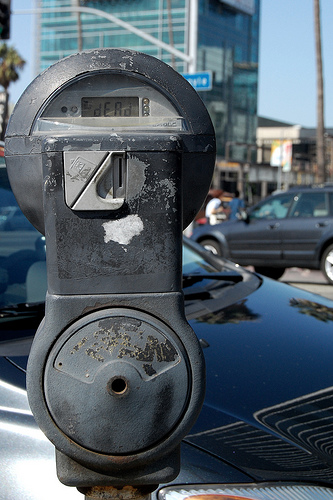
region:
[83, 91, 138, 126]
word on the meter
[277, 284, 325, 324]
reflection in the car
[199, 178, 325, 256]
car near another car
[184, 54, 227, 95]
sign near the meter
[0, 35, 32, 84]
tree near the car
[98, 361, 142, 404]
hole in the meter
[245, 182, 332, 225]
windows on side of car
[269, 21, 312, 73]
sky above the land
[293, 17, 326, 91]
branch of a tree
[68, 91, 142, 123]
"dEAd" is written on the meter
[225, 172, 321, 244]
Vehicle in the background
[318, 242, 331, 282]
Wheel of a vehicle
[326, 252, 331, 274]
Rim of a tire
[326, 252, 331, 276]
Silver rim of a tire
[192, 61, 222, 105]
Street sign in the distance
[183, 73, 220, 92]
The sign has white lettering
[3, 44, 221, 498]
black parking meter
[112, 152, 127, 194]
coin slot on parking meter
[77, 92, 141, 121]
digital window on parking meter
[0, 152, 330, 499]
car parked behind parking meter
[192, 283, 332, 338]
reflection of trees in hood of car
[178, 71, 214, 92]
blue and white street sign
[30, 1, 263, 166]
tall metal and glass building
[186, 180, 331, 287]
grey four door suv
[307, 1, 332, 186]
tall wooden pole upright on sidewalk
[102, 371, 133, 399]
hole in center of bottom of parking meter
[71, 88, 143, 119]
word dead on the parking meter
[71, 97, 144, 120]
word dead on the parking meter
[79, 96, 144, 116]
word dead on the parking meter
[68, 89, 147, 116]
word dead on the parking meter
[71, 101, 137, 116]
word dead on the parking meter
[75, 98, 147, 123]
word dead on the parking meter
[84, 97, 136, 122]
word dead on the parking meter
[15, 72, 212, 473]
the parking mete is gray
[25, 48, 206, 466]
the parking mete is gray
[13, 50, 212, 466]
the parking mete is gray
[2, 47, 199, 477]
the parking mete is gray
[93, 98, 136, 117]
letters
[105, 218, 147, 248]
white paper on the meter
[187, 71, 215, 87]
a blue sign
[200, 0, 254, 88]
a building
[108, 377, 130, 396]
a small hole on the meter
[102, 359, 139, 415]
a hole in the meter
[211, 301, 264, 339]
a green tree in he reflection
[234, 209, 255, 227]
the suv mirror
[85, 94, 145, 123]
the sign says dead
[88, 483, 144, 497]
the meter is rusted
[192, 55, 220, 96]
a blue sign in the background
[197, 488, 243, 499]
the headlight of the car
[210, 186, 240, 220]
people in the background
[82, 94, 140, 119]
digital screen on the parking meter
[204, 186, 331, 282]
dark grey suv on the street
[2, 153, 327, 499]
car behind the parking meter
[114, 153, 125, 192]
coin slot on the parking meter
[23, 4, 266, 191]
tall building behind the parking meter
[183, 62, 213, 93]
blue and white street sign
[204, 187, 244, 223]
people walking behind the suv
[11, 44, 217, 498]
gray parking meter on a post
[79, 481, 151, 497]
post the parking meter is on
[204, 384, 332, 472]
reflection on the car hood